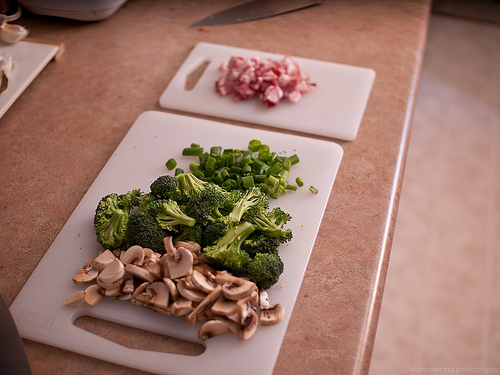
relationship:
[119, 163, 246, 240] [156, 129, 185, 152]
brocolli on board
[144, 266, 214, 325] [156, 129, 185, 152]
mushrooms on board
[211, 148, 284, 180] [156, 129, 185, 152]
chives on board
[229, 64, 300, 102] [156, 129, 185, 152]
meat on board